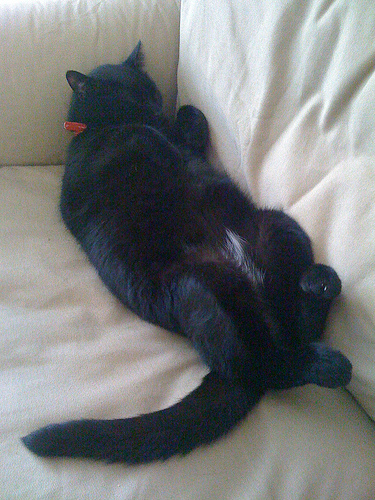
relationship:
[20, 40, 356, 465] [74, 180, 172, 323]
cat resting on back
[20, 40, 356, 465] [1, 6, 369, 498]
cat on sofa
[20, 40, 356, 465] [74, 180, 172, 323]
cat has back